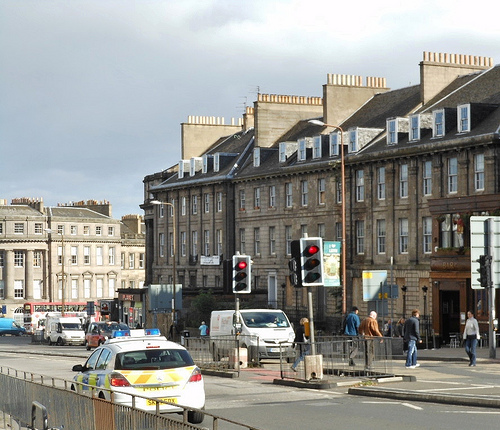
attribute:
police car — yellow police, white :
[66, 332, 210, 421]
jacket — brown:
[355, 313, 385, 336]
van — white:
[207, 305, 298, 367]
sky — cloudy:
[1, 12, 483, 196]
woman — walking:
[450, 312, 489, 364]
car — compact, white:
[73, 330, 204, 422]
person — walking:
[408, 308, 424, 368]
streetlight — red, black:
[294, 237, 322, 285]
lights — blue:
[108, 318, 161, 336]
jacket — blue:
[343, 313, 359, 333]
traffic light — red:
[302, 238, 321, 257]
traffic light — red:
[234, 252, 251, 271]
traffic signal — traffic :
[302, 239, 331, 284]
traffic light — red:
[226, 246, 254, 298]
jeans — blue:
[402, 339, 418, 371]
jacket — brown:
[392, 294, 438, 340]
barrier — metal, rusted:
[60, 378, 207, 425]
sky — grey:
[5, 3, 497, 223]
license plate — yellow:
[125, 395, 206, 419]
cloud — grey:
[1, 3, 324, 196]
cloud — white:
[163, 1, 484, 92]